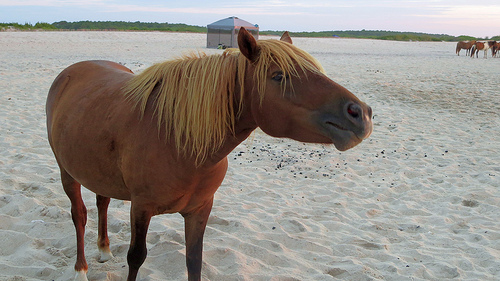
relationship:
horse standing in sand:
[31, 21, 378, 280] [10, 227, 461, 271]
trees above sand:
[4, 18, 205, 32] [0, 31, 207, 57]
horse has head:
[31, 21, 378, 280] [226, 16, 385, 166]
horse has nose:
[31, 21, 378, 280] [340, 94, 370, 123]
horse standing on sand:
[31, 21, 378, 280] [10, 227, 461, 271]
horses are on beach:
[449, 35, 499, 61] [3, 27, 499, 280]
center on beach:
[206, 16, 258, 49] [3, 27, 499, 280]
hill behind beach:
[0, 19, 500, 41] [3, 27, 499, 280]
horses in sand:
[449, 35, 499, 61] [365, 38, 498, 88]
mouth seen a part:
[327, 114, 367, 145] [316, 100, 366, 151]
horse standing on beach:
[31, 21, 378, 280] [3, 27, 499, 280]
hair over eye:
[254, 37, 321, 92] [271, 72, 291, 83]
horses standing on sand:
[449, 35, 499, 61] [10, 227, 461, 271]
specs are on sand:
[257, 148, 322, 181] [252, 151, 495, 276]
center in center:
[206, 16, 258, 49] [184, 14, 302, 59]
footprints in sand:
[252, 151, 495, 276] [3, 27, 499, 280]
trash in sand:
[234, 131, 459, 187] [3, 27, 499, 280]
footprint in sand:
[204, 247, 241, 277] [3, 27, 499, 280]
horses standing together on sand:
[449, 35, 499, 61] [3, 27, 499, 280]